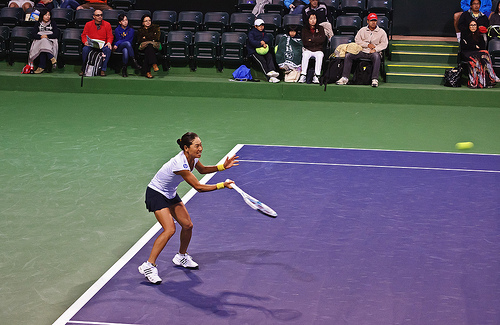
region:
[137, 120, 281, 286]
the tennis player on the court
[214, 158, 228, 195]
the yellow bands on the womens wrist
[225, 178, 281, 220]
the white and black frame of the racquet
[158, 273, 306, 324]
the shadow of the player on the court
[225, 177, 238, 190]
the hand grabbing the racquets handle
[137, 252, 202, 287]
the white tennis shoes on the court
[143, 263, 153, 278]
the three black stripes for the adidas shoe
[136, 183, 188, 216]
the black skirt on the player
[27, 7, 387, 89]
the people watching the match in their seats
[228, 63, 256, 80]
the blue bag on the ground by the seats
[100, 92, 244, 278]
WOMAN ON TENNIS COURT PLAYING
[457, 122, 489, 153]
GREEN TENNIS BALL IN MOTION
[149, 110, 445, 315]
PURPLE SURFACE OF COURT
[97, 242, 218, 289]
WHITE ADIDAS ON WOMAN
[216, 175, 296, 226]
WHITE RACKET IN HAND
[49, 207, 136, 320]
WHITE LINES ON TENNIS COURT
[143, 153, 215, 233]
BLACK SKIRT ON TENNIS PLAYER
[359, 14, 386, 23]
RED CAP ON OBSERVER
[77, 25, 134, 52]
RED SWEATER ON OBSERVER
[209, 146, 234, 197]
YELLOW WRISTBANDS ON PLAYER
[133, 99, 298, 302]
a lady with a racket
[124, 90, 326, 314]
she is smilling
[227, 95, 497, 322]
the court is purple in colour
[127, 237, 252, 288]
she has white sports shoes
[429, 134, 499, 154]
the ball is green in colour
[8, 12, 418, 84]
spectators are seated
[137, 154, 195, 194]
she has a white jersey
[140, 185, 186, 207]
her shorts are black in colour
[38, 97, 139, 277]
the lawn is green in colour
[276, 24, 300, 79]
the spectator has covered herself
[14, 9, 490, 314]
Photo taken during a tennis match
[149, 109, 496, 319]
Purple tennis court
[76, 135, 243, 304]
White lines on the court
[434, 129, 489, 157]
Tennis ball in the air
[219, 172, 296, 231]
Tennis racket in the right hand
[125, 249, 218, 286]
White sneakers on the woman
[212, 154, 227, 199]
Sweatbands on the wrists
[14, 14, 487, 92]
Spectators in their seats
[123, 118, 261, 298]
Woman tennis player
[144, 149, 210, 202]
White shirt on the woman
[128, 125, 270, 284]
tennis player standing on blue court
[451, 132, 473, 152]
yellow tennis ball moving through the air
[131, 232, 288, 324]
shadow of tennis player on court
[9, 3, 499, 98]
people watching the tennis match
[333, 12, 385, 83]
man wearing red hat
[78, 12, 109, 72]
man wearing red shirt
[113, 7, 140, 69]
woman wearing blue shirt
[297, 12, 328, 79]
person wearing white pants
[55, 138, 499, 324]
white lines on tennis court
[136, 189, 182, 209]
black skirt of tennis player